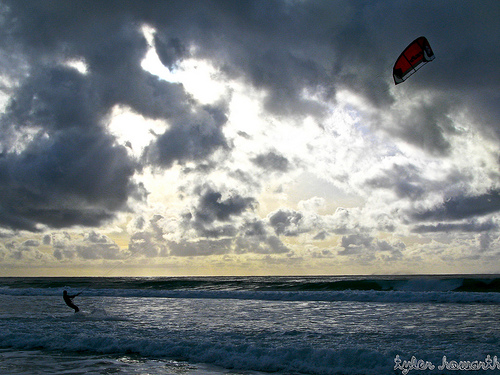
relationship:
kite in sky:
[367, 32, 453, 96] [70, 17, 343, 222]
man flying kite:
[49, 278, 90, 320] [367, 32, 453, 96]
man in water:
[49, 278, 90, 320] [181, 270, 346, 351]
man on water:
[49, 278, 90, 320] [181, 270, 346, 351]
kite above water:
[367, 32, 453, 96] [181, 270, 346, 351]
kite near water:
[367, 32, 453, 96] [181, 270, 346, 351]